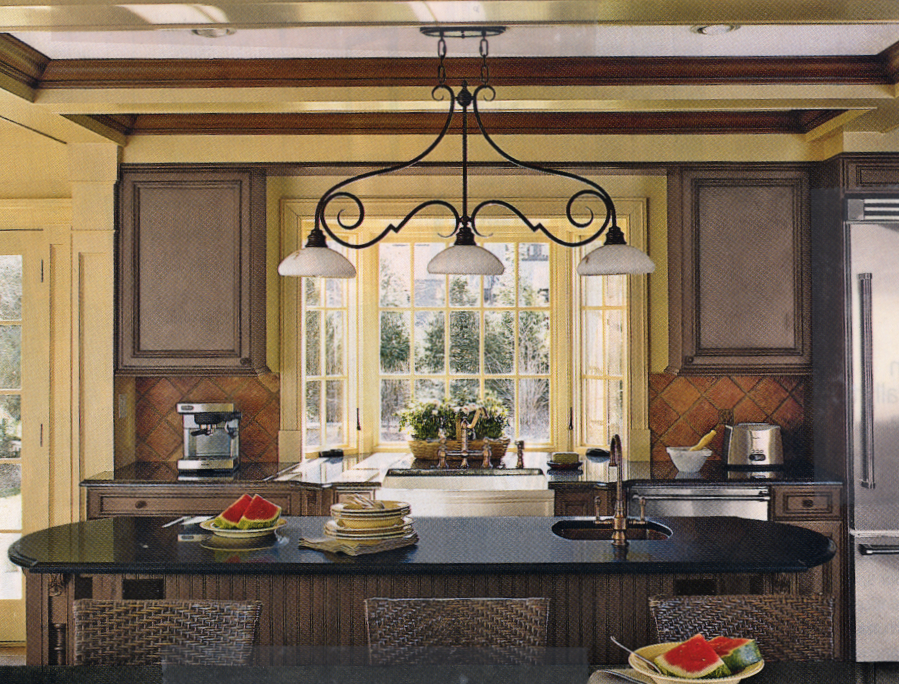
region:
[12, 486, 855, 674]
A kitchen island.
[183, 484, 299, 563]
Sliced up watermelon on a plate.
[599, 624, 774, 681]
A bowl of watermelon slices resting on top of the table.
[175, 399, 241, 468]
An espresso maker.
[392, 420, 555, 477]
A kitchen sink area.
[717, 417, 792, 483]
A stainless steel appliance on top of the counter.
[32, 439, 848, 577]
Black countertops.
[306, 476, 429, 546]
A stack of dishes.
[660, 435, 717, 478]
A white bowl.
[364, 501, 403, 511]
plate on the table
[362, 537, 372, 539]
plate on the table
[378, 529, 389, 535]
plate on the table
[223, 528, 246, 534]
plate on the table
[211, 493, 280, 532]
watermelon on a plate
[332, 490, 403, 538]
a stack of plates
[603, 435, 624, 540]
the faucet on the sink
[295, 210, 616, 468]
a window in the room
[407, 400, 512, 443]
a plant in the window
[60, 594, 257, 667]
a wicker chair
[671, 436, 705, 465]
a small white bowl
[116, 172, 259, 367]
a wooden cabinet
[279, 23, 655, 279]
black wrought iron hanging lamp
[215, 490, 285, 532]
two slices of red watermelon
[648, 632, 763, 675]
two slices of red watermelon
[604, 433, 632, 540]
bronze metal kitchen faucet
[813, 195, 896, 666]
stainless steel refrigerator and freezer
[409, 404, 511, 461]
decorative plants in a planter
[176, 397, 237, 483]
stainless steel espresso maker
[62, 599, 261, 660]
brown wicker wood back of a chair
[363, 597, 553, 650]
brown wicker wood back of a chair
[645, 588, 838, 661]
brown wicker wood back of a chair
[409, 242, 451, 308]
A window on a building.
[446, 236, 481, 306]
A window on a building.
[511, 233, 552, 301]
A window on a building.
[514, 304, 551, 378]
A window on a building.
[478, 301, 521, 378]
A window on a building.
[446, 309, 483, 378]
A window on a building.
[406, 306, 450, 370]
A window on a building.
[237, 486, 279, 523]
a slice of watermelon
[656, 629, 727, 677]
a slice of watermelon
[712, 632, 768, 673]
a slice of watermelon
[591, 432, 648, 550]
a kitchen sink faucet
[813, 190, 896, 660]
a brushed aluminum refrigerator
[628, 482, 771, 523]
a built in dishwasher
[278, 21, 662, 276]
an overhead island light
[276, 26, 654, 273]
Iron chandelier with three lights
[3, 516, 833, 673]
wooden kitchen island with black counter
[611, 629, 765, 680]
watermelon wedges in yellow bowl with spoon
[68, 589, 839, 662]
woven backed kitchen chairs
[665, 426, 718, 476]
white mixing bowl with yellow handled utensil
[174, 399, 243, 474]
silver and black espresso maker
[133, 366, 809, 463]
orange and red tiled backsplash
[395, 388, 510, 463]
yellow flowering potted plants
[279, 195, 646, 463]
bay window with yellow trim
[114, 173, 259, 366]
a brown cabinet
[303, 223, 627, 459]
a window in the room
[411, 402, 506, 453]
plants in front of the window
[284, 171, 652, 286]
lights hanging from the ceiling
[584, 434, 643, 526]
the faucet on the sink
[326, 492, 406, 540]
a stack of plates